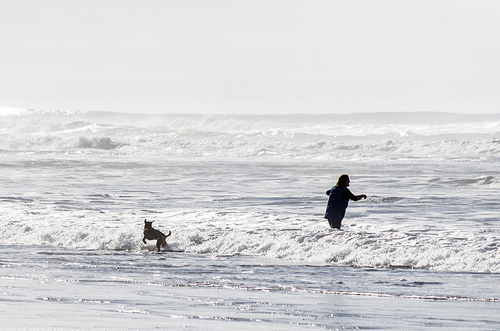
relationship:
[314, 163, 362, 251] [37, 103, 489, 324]
person standing in beach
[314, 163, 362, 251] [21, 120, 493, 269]
person standing in water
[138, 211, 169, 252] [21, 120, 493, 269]
dog jumping in water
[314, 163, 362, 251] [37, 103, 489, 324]
person in beach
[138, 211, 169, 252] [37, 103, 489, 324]
dog in beach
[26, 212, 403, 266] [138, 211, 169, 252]
waves near dog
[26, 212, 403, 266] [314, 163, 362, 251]
waves next to person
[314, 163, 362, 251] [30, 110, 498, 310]
person in ocean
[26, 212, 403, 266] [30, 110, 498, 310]
waves in ocean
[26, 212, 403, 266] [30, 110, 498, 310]
waves inside of ocean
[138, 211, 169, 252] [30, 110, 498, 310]
dog in ocean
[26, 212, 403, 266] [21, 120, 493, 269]
waves inside water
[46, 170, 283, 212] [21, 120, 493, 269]
ripples in water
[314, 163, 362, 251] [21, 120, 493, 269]
person inside water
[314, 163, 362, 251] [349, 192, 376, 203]
person has arm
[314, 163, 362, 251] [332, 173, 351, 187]
person has head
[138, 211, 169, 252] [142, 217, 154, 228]
dog has head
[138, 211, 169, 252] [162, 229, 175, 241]
dog has tail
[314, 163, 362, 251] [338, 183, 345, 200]
person has torso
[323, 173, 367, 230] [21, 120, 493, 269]
person standing in water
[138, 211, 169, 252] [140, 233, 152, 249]
dog has feet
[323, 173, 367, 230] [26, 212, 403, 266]
person near waves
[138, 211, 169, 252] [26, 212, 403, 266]
dog near waves